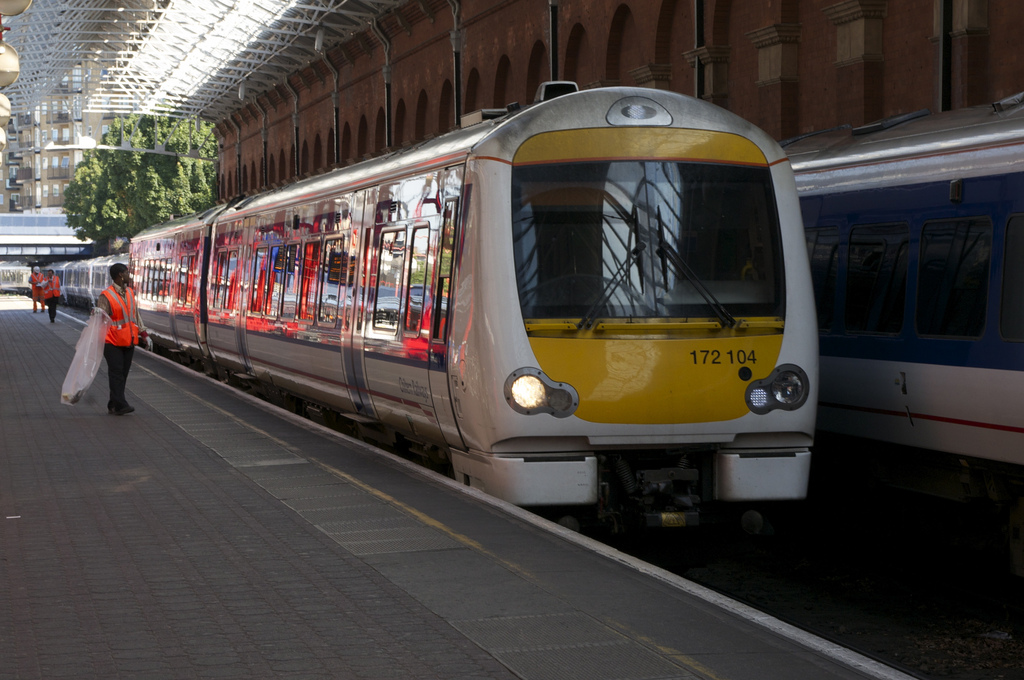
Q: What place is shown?
A: It is a station.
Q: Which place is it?
A: It is a station.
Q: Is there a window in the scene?
A: Yes, there is a window.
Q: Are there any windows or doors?
A: Yes, there is a window.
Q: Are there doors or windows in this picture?
A: Yes, there is a window.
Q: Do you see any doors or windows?
A: Yes, there is a window.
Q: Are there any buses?
A: No, there are no buses.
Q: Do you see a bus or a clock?
A: No, there are no buses or clocks.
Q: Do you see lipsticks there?
A: No, there are no lipsticks.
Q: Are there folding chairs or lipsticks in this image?
A: No, there are no lipsticks or folding chairs.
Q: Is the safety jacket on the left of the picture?
A: Yes, the safety jacket is on the left of the image.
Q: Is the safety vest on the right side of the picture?
A: No, the safety vest is on the left of the image.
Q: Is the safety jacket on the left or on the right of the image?
A: The safety jacket is on the left of the image.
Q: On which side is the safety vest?
A: The safety vest is on the left of the image.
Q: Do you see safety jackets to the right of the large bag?
A: Yes, there is a safety jacket to the right of the bag.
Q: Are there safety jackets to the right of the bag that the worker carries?
A: Yes, there is a safety jacket to the right of the bag.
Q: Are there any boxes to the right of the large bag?
A: No, there is a safety jacket to the right of the bag.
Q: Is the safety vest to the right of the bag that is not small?
A: Yes, the safety vest is to the right of the bag.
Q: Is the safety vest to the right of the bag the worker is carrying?
A: Yes, the safety vest is to the right of the bag.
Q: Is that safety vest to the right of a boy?
A: No, the safety vest is to the right of the bag.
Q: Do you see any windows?
A: Yes, there are windows.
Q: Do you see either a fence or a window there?
A: Yes, there are windows.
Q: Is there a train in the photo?
A: Yes, there is a train.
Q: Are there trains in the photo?
A: Yes, there is a train.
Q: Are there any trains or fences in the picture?
A: Yes, there is a train.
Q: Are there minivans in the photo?
A: No, there are no minivans.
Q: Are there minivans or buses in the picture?
A: No, there are no minivans or buses.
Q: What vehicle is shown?
A: The vehicle is a train.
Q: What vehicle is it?
A: The vehicle is a train.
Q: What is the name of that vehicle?
A: That is a train.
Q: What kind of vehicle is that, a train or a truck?
A: That is a train.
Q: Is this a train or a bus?
A: This is a train.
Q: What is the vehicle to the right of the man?
A: The vehicle is a train.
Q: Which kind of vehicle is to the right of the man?
A: The vehicle is a train.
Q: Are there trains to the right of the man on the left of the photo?
A: Yes, there is a train to the right of the man.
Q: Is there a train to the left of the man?
A: No, the train is to the right of the man.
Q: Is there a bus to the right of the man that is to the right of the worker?
A: No, there is a train to the right of the man.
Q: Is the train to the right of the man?
A: Yes, the train is to the right of the man.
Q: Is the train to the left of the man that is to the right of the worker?
A: No, the train is to the right of the man.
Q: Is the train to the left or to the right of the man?
A: The train is to the right of the man.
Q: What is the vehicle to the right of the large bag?
A: The vehicle is a train.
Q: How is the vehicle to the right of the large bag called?
A: The vehicle is a train.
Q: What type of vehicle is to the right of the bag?
A: The vehicle is a train.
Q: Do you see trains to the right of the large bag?
A: Yes, there is a train to the right of the bag.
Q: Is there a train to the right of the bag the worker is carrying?
A: Yes, there is a train to the right of the bag.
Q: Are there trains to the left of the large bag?
A: No, the train is to the right of the bag.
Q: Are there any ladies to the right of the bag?
A: No, there is a train to the right of the bag.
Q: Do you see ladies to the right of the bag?
A: No, there is a train to the right of the bag.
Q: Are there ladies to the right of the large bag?
A: No, there is a train to the right of the bag.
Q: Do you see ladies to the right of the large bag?
A: No, there is a train to the right of the bag.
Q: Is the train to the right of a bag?
A: Yes, the train is to the right of a bag.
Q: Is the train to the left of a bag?
A: No, the train is to the right of a bag.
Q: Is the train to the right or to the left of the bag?
A: The train is to the right of the bag.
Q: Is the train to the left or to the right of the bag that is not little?
A: The train is to the right of the bag.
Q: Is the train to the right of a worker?
A: Yes, the train is to the right of a worker.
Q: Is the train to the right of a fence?
A: No, the train is to the right of a worker.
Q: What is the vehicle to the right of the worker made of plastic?
A: The vehicle is a train.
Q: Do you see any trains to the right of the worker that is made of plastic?
A: Yes, there is a train to the right of the worker.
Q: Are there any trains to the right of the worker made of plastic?
A: Yes, there is a train to the right of the worker.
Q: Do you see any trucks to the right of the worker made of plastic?
A: No, there is a train to the right of the worker.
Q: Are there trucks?
A: No, there are no trucks.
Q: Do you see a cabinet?
A: No, there are no cabinets.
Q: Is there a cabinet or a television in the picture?
A: No, there are no cabinets or televisions.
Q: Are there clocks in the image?
A: No, there are no clocks.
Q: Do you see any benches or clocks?
A: No, there are no clocks or benches.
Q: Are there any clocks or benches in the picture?
A: No, there are no clocks or benches.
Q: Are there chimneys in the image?
A: No, there are no chimneys.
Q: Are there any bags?
A: Yes, there is a bag.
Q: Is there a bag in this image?
A: Yes, there is a bag.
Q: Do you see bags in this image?
A: Yes, there is a bag.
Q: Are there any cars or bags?
A: Yes, there is a bag.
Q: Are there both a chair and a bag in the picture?
A: No, there is a bag but no chairs.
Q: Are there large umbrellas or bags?
A: Yes, there is a large bag.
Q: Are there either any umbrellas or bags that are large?
A: Yes, the bag is large.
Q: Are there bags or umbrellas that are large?
A: Yes, the bag is large.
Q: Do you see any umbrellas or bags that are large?
A: Yes, the bag is large.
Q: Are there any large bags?
A: Yes, there is a large bag.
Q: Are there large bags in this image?
A: Yes, there is a large bag.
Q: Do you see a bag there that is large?
A: Yes, there is a large bag.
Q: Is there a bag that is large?
A: Yes, there is a bag that is large.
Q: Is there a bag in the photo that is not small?
A: Yes, there is a large bag.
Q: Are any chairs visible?
A: No, there are no chairs.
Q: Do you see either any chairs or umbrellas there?
A: No, there are no chairs or umbrellas.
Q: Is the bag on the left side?
A: Yes, the bag is on the left of the image.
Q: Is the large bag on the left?
A: Yes, the bag is on the left of the image.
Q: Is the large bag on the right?
A: No, the bag is on the left of the image.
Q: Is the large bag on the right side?
A: No, the bag is on the left of the image.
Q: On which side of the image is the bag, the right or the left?
A: The bag is on the left of the image.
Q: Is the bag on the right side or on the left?
A: The bag is on the left of the image.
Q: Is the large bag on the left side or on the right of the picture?
A: The bag is on the left of the image.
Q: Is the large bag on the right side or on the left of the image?
A: The bag is on the left of the image.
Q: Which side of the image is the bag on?
A: The bag is on the left of the image.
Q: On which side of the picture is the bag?
A: The bag is on the left of the image.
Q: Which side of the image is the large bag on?
A: The bag is on the left of the image.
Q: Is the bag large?
A: Yes, the bag is large.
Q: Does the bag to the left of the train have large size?
A: Yes, the bag is large.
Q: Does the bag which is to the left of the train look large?
A: Yes, the bag is large.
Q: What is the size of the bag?
A: The bag is large.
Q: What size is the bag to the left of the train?
A: The bag is large.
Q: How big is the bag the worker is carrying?
A: The bag is large.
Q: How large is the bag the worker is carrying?
A: The bag is large.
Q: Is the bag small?
A: No, the bag is large.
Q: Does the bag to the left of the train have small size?
A: No, the bag is large.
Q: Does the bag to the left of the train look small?
A: No, the bag is large.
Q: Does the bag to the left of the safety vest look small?
A: No, the bag is large.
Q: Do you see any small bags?
A: No, there is a bag but it is large.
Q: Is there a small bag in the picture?
A: No, there is a bag but it is large.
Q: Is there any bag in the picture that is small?
A: No, there is a bag but it is large.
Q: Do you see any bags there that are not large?
A: No, there is a bag but it is large.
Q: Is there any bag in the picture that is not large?
A: No, there is a bag but it is large.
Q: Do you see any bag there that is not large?
A: No, there is a bag but it is large.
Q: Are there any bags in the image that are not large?
A: No, there is a bag but it is large.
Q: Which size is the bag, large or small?
A: The bag is large.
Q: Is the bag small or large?
A: The bag is large.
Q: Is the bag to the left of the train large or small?
A: The bag is large.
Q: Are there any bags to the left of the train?
A: Yes, there is a bag to the left of the train.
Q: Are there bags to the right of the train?
A: No, the bag is to the left of the train.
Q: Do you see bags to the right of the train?
A: No, the bag is to the left of the train.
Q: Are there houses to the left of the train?
A: No, there is a bag to the left of the train.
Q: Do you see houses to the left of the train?
A: No, there is a bag to the left of the train.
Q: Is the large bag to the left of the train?
A: Yes, the bag is to the left of the train.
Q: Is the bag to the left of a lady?
A: No, the bag is to the left of the train.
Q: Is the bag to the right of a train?
A: No, the bag is to the left of a train.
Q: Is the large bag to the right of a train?
A: No, the bag is to the left of a train.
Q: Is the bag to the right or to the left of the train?
A: The bag is to the left of the train.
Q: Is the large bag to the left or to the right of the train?
A: The bag is to the left of the train.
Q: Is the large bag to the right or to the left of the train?
A: The bag is to the left of the train.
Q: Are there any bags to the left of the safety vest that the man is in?
A: Yes, there is a bag to the left of the safety jacket.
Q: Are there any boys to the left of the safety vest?
A: No, there is a bag to the left of the safety vest.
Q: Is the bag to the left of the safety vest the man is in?
A: Yes, the bag is to the left of the safety vest.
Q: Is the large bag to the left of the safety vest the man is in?
A: Yes, the bag is to the left of the safety vest.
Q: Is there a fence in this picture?
A: No, there are no fences.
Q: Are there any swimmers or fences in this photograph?
A: No, there are no fences or swimmers.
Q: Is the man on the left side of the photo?
A: Yes, the man is on the left of the image.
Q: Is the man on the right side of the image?
A: No, the man is on the left of the image.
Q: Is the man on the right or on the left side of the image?
A: The man is on the left of the image.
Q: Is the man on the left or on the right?
A: The man is on the left of the image.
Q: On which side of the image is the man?
A: The man is on the left of the image.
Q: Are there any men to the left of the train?
A: Yes, there is a man to the left of the train.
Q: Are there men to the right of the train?
A: No, the man is to the left of the train.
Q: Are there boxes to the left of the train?
A: No, there is a man to the left of the train.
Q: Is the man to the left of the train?
A: Yes, the man is to the left of the train.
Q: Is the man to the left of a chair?
A: No, the man is to the left of the train.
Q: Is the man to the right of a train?
A: No, the man is to the left of a train.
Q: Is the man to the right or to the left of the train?
A: The man is to the left of the train.